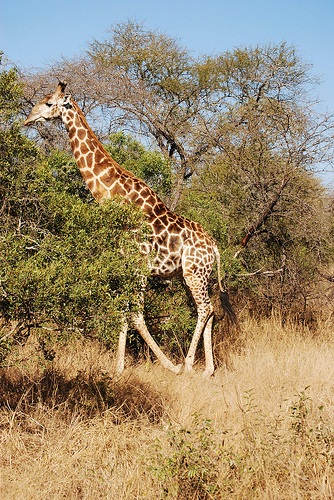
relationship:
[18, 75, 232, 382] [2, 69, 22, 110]
giraffe grazing on leaves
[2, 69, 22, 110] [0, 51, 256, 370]
leaves on tree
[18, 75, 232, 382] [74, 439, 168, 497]
giraffe on grass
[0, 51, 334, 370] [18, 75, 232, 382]
tree near giraffe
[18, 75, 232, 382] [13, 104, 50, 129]
giraffe has nose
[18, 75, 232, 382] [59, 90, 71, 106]
giraffe has ear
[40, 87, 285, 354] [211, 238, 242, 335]
giraffe has tail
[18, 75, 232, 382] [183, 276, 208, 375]
giraffe has leg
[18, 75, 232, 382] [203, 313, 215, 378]
giraffe has leg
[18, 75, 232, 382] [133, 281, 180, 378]
giraffe has leg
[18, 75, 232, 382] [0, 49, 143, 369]
giraffe munching on leaves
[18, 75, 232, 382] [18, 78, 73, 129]
giraffe has head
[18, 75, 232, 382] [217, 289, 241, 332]
giraffe has black tail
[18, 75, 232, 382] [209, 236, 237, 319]
giraffe has tail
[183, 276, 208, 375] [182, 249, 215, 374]
leg longer legs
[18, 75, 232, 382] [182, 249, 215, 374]
giraffe has legs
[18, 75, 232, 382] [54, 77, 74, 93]
giraffe has horns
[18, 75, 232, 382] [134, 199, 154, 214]
giraffe has spots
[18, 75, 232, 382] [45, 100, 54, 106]
giraffe has eye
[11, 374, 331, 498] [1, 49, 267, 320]
grass around giraffe